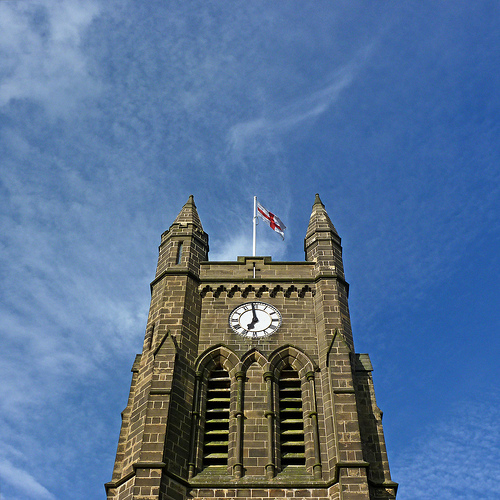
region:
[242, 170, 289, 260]
a red and white flag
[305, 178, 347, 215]
the left point on top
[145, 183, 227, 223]
the right tip of top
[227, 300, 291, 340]
a round clock on building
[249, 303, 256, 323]
the minute hand on clock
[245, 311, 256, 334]
the hour hand of clock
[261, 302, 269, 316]
the number one on clock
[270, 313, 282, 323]
the number three on clock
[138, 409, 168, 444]
bricks on the building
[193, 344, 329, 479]
two windows on building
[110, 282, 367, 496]
white clock on tower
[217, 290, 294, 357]
clock has roman numerals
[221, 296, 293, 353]
roman numerals are black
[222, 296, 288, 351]
clock has white face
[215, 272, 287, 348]
clock has black hands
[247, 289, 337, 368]
brown brick exterior of tower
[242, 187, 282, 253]
England flag on tower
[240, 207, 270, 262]
flag on white pole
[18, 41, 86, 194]
blue and white sky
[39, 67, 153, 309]
thin clouds in sky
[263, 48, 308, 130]
part of a cloud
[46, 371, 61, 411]
part fo a cloyud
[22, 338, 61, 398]
part of a cloud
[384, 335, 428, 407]
part of a cloud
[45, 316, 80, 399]
part of a cloud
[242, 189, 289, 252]
the flag on the tower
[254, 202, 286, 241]
the flag waving in the wind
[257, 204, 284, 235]
the red cross on the flag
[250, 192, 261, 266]
the white pole on the tower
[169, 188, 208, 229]
the spire of the tower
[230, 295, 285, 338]
the white face of the clock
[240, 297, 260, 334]
the black hands of the clock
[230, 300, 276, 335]
the black roman numerials on the clock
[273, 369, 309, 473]
the slits in the window on the tower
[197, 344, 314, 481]
the windows on the brick tower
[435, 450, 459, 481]
part of a cloud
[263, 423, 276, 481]
part of a pillar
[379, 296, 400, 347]
part of a cloud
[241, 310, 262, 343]
part of a clock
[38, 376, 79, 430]
part of a cloud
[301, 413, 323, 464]
p-art of a pillar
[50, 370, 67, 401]
part of a cloud